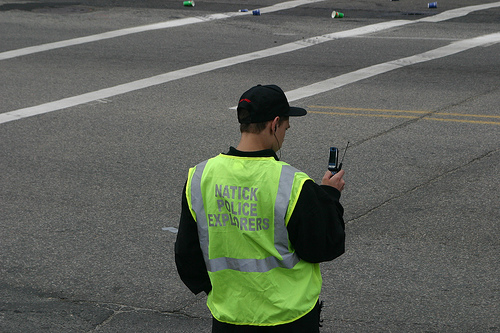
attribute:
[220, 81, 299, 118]
hat — black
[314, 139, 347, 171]
phone — black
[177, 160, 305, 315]
vest — yellow, yellowy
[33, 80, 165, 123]
line — white